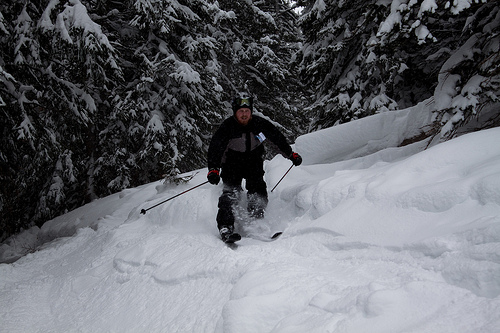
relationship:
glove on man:
[207, 167, 221, 184] [197, 89, 311, 251]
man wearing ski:
[197, 89, 311, 251] [265, 227, 284, 242]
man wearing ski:
[197, 89, 311, 251] [224, 227, 240, 246]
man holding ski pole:
[197, 89, 311, 251] [138, 161, 304, 215]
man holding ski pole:
[197, 89, 311, 251] [138, 179, 210, 216]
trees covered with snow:
[422, 3, 491, 130] [309, 174, 496, 329]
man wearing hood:
[197, 89, 311, 251] [232, 94, 254, 109]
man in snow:
[197, 89, 311, 251] [3, 93, 497, 331]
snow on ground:
[3, 99, 498, 331] [310, 209, 422, 269]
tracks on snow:
[308, 278, 394, 318] [64, 245, 486, 312]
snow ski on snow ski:
[259, 215, 305, 263] [214, 214, 260, 265]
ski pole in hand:
[138, 161, 304, 215] [204, 176, 224, 185]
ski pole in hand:
[138, 161, 304, 215] [289, 149, 304, 167]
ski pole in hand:
[138, 179, 210, 216] [208, 170, 221, 184]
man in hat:
[197, 89, 311, 251] [229, 94, 254, 111]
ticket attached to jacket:
[253, 129, 273, 145] [218, 123, 286, 174]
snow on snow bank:
[3, 93, 497, 331] [35, 216, 245, 302]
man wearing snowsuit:
[197, 89, 311, 251] [220, 119, 272, 218]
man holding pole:
[197, 89, 311, 251] [131, 139, 329, 221]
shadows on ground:
[235, 212, 293, 258] [102, 259, 273, 278]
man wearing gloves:
[197, 89, 311, 251] [201, 145, 308, 194]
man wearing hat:
[197, 65, 313, 304] [229, 94, 254, 111]